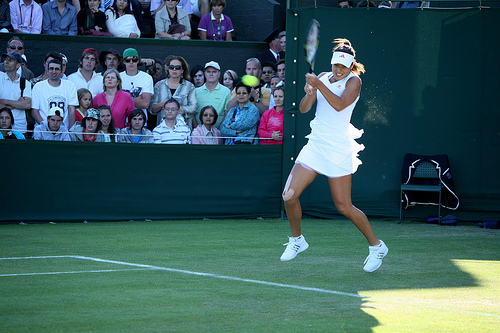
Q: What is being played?
A: Tennis.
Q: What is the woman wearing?
A: Visor.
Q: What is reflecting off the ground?
A: Sunlgiht.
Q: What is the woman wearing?
A: Visor.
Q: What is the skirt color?
A: White.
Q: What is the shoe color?
A: White.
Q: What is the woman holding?
A: Racket.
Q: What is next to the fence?
A: Chair.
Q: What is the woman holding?
A: Racket.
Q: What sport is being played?
A: Tennis.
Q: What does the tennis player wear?
A: White skirt and hat.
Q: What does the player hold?
A: A tennis racket.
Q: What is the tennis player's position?
A: Above the ground.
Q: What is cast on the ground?
A: A shadow is cast on the ground.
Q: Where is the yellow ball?
A: In the air.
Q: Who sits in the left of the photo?
A: Spectators.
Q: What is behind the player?
A: A chair.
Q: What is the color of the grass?
A: Green.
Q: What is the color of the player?
A: White.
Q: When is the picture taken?
A: Daytime.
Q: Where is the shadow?
A: In the ground.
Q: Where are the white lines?
A: Ground.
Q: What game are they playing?
A: Tennis.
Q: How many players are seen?
A: 1.